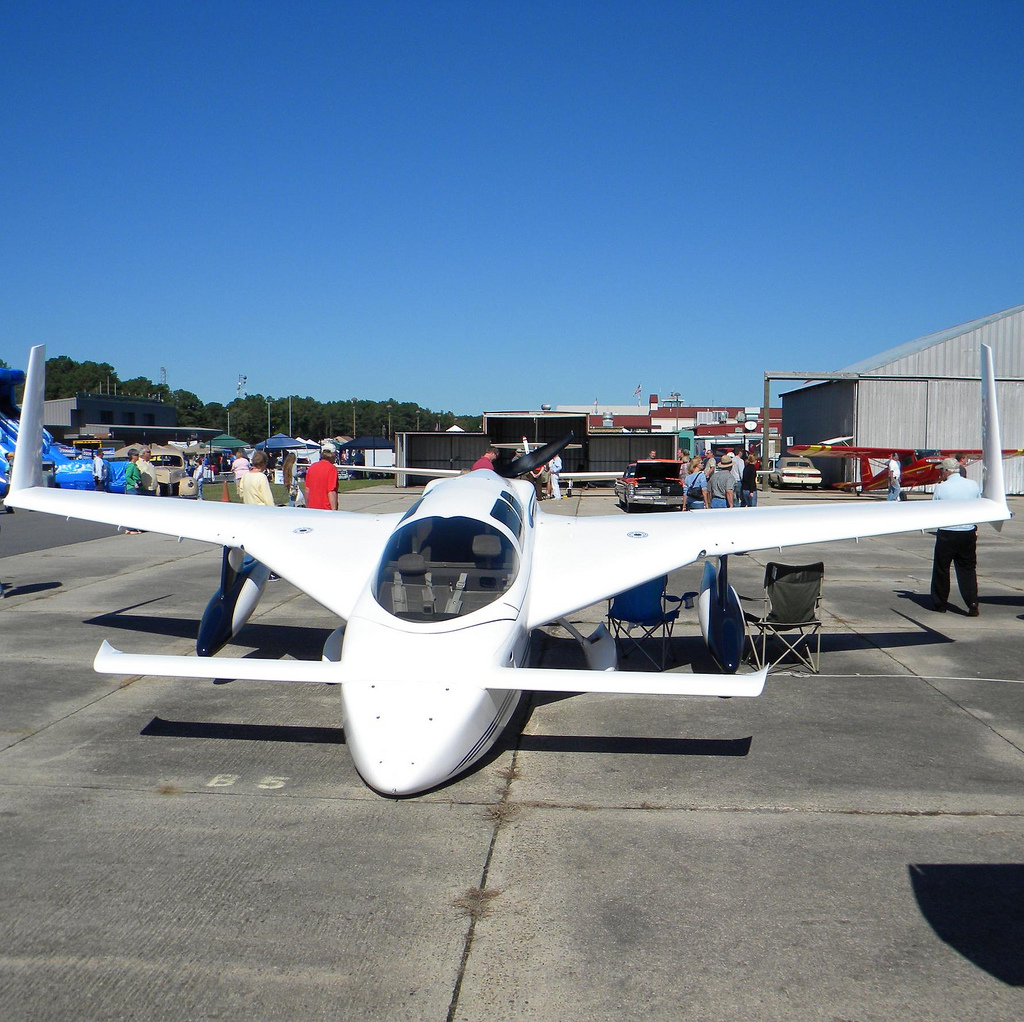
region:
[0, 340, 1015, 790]
A white aircraft on the ground.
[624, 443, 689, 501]
The car with an opened bonnet.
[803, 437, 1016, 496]
The red aircraft in the background.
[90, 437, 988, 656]
A group of people in an aerodrome.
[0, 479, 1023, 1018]
The cemented gray surface.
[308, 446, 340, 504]
The man in a red shirt.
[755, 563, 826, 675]
A chair next to the aircraft.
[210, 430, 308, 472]
The blue and green umbrellas in the background.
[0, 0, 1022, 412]
A cloudless blue sky.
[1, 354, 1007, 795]
A white plane on the ground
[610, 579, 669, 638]
a blue chair under the plane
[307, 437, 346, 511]
A man in a red shirt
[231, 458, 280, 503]
A person in a yellow shirt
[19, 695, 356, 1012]
A concrete ground with the number B5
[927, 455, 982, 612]
Man with his back turned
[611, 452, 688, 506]
A little red car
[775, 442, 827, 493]
The back of a white car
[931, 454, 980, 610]
A man in a blue shirt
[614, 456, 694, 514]
car with open hood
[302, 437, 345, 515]
man wearing a red shirt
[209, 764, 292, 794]
letters and numbers painted on the ground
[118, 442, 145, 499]
woman wearing green shirt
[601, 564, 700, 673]
blue folding chair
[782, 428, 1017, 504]
small red air plane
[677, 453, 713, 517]
woman wearing light blue shirt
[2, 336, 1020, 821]
small white air plane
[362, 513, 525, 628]
front windshield of airplane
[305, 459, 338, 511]
a man's short sleeve red shirt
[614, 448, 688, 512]
the front of an old red car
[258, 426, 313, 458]
a blue tent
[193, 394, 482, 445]
a row of green trees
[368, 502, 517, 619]
front window of a plane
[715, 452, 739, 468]
a brown and black hat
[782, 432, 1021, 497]
a small red and yellow plane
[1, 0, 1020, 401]
a large blue sky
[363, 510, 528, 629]
front window of airplane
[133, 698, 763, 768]
shadow of airplane wing on tarmac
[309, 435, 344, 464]
white baseball cap on person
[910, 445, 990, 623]
man in black pants walking across tarmac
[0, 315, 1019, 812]
white plane parked on tarmac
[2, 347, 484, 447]
line of green trees in background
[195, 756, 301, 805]
letter and number combination "b5" in white writing on tarmac